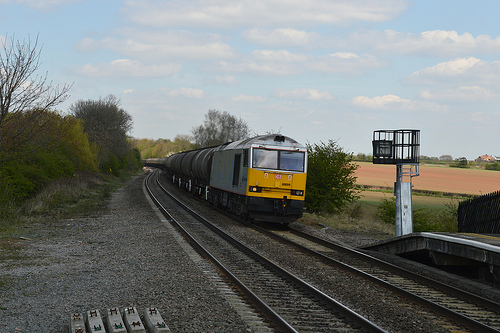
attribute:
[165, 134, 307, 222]
train — yellow, freight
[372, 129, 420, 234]
lift — metal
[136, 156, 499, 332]
tracks — black, steel, rusted, on the ground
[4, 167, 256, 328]
stones — these, on ground, on the ground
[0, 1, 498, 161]
sky — blue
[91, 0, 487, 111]
clouds — white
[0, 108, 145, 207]
bushes — these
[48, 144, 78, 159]
leaves — green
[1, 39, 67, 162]
tree — empty, leafless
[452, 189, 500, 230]
fence — wood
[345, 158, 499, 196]
field — brown